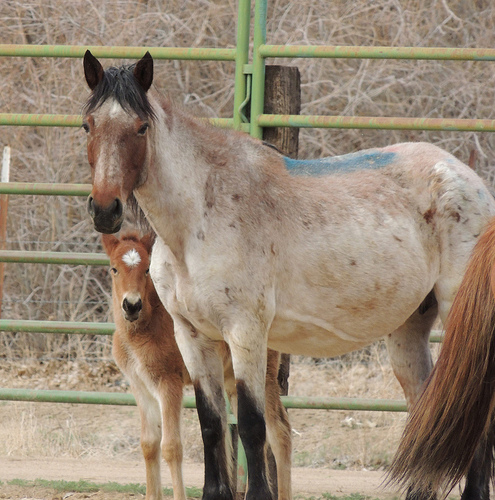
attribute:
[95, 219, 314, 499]
horse — young, staring, brown, baby, small, looking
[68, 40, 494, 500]
horse — staring, white, big, brown, adult, looking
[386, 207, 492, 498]
tail — brown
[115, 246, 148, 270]
spot — white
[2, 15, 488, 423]
fence — green, rusted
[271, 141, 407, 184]
mark — blue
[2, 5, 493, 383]
grass — dry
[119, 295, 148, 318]
nose — black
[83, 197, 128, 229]
nose — black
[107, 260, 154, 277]
eyes — open, black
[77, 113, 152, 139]
eyes — open, black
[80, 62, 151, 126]
hair — black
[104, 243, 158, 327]
face — brown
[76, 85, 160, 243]
face — brown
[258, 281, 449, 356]
stomach — white